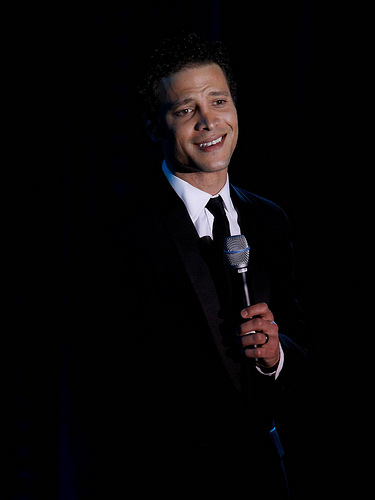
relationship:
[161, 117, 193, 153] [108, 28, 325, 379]
cheek of man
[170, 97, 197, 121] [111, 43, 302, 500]
eye on face of man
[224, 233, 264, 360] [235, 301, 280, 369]
mic in hand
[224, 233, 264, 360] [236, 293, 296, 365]
mic in hands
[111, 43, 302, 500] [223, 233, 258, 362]
man holding microphone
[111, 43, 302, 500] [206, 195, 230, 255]
man wearing tie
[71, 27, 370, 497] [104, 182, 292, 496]
man wearing suit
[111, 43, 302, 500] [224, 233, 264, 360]
man holding mic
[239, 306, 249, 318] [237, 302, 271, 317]
fingernail on finger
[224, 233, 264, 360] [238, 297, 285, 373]
mic on hands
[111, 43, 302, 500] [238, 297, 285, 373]
man has hands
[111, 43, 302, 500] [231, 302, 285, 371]
man has hands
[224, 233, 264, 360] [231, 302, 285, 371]
mic in hands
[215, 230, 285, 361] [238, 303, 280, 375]
mic in hands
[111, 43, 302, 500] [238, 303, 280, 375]
man has hands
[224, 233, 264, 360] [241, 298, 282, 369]
mic in hand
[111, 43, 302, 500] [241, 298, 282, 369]
man has hand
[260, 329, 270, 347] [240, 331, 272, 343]
ring on finger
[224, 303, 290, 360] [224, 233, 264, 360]
hand holding mic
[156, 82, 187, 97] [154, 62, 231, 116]
vein on forehead